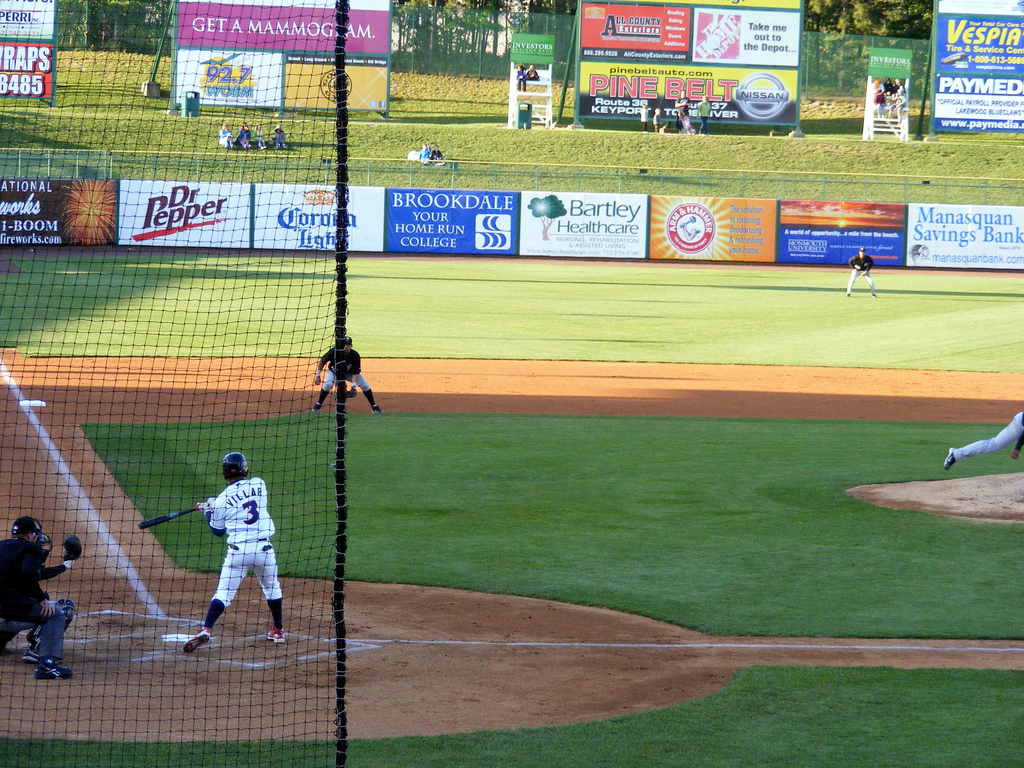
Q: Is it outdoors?
A: Yes, it is outdoors.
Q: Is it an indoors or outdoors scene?
A: It is outdoors.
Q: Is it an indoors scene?
A: No, it is outdoors.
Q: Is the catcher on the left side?
A: Yes, the catcher is on the left of the image.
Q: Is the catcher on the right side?
A: No, the catcher is on the left of the image.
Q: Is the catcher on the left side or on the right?
A: The catcher is on the left of the image.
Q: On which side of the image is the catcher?
A: The catcher is on the left of the image.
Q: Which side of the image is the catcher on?
A: The catcher is on the left of the image.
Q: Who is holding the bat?
A: The catcher is holding the bat.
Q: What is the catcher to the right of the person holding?
A: The catcher is holding the bat.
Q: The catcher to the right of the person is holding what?
A: The catcher is holding the bat.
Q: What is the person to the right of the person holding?
A: The catcher is holding the bat.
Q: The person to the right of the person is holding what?
A: The catcher is holding the bat.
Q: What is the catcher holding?
A: The catcher is holding the bat.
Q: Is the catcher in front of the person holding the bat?
A: Yes, the catcher is holding the bat.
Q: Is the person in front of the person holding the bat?
A: Yes, the catcher is holding the bat.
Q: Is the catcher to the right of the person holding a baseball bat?
A: No, the catcher is holding the bat.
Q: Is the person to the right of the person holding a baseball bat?
A: No, the catcher is holding the bat.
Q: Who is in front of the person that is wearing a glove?
A: The catcher is in front of the person.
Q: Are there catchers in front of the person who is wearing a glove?
A: Yes, there is a catcher in front of the person.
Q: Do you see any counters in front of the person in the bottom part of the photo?
A: No, there is a catcher in front of the person.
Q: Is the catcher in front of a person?
A: Yes, the catcher is in front of a person.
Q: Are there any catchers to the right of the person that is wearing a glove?
A: Yes, there is a catcher to the right of the person.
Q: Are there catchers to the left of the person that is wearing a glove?
A: No, the catcher is to the right of the person.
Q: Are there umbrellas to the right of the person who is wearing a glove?
A: No, there is a catcher to the right of the person.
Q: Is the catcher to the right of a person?
A: Yes, the catcher is to the right of a person.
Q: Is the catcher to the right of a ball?
A: No, the catcher is to the right of a person.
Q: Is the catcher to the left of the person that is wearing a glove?
A: No, the catcher is to the right of the person.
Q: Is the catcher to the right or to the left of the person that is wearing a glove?
A: The catcher is to the right of the person.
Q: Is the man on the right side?
A: Yes, the man is on the right of the image.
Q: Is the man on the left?
A: No, the man is on the right of the image.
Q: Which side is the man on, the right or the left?
A: The man is on the right of the image.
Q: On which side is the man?
A: The man is on the right of the image.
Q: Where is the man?
A: The man is in the field.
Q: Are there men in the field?
A: Yes, there is a man in the field.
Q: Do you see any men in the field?
A: Yes, there is a man in the field.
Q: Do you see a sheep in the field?
A: No, there is a man in the field.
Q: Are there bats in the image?
A: Yes, there is a bat.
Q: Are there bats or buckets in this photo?
A: Yes, there is a bat.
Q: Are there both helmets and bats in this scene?
A: Yes, there are both a bat and a helmet.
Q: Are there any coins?
A: No, there are no coins.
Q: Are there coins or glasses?
A: No, there are no coins or glasses.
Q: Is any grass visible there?
A: Yes, there is grass.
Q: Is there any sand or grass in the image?
A: Yes, there is grass.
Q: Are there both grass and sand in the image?
A: No, there is grass but no sand.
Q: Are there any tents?
A: No, there are no tents.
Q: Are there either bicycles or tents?
A: No, there are no tents or bicycles.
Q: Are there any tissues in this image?
A: No, there are no tissues.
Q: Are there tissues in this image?
A: No, there are no tissues.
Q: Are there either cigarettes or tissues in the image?
A: No, there are no tissues or cigarettes.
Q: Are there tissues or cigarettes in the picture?
A: No, there are no tissues or cigarettes.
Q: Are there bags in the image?
A: No, there are no bags.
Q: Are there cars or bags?
A: No, there are no bags or cars.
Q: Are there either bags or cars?
A: No, there are no bags or cars.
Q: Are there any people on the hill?
A: Yes, there are people on the hill.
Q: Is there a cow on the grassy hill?
A: No, there are people on the hill.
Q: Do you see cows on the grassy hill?
A: No, there are people on the hill.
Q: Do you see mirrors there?
A: No, there are no mirrors.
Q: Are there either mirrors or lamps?
A: No, there are no mirrors or lamps.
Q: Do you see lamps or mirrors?
A: No, there are no mirrors or lamps.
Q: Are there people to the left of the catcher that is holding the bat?
A: Yes, there is a person to the left of the catcher.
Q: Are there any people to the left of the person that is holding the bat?
A: Yes, there is a person to the left of the catcher.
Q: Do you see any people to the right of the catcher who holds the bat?
A: No, the person is to the left of the catcher.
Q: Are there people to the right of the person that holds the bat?
A: No, the person is to the left of the catcher.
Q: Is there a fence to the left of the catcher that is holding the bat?
A: No, there is a person to the left of the catcher.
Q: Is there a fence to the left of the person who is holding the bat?
A: No, there is a person to the left of the catcher.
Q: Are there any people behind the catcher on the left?
A: Yes, there is a person behind the catcher.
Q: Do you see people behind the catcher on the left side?
A: Yes, there is a person behind the catcher.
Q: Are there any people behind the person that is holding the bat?
A: Yes, there is a person behind the catcher.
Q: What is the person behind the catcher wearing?
A: The person is wearing a glove.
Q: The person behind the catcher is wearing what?
A: The person is wearing a glove.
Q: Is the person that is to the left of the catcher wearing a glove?
A: Yes, the person is wearing a glove.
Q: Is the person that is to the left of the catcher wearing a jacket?
A: No, the person is wearing a glove.